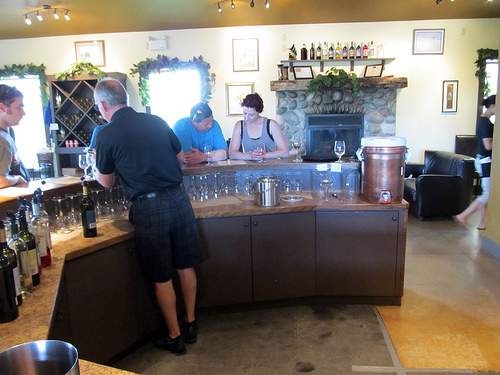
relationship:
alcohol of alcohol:
[79, 176, 97, 237] [81, 185, 96, 237]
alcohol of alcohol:
[31, 197, 51, 266] [29, 203, 54, 262]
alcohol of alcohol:
[14, 209, 40, 287] [14, 216, 43, 288]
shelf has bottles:
[277, 56, 389, 64] [296, 44, 374, 56]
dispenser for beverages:
[358, 138, 410, 204] [364, 178, 405, 206]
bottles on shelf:
[296, 44, 374, 56] [277, 56, 389, 64]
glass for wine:
[55, 196, 75, 238] [87, 199, 98, 235]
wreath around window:
[142, 60, 214, 81] [137, 52, 213, 113]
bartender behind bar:
[92, 87, 203, 348] [15, 176, 421, 215]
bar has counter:
[15, 176, 421, 215] [184, 153, 404, 171]